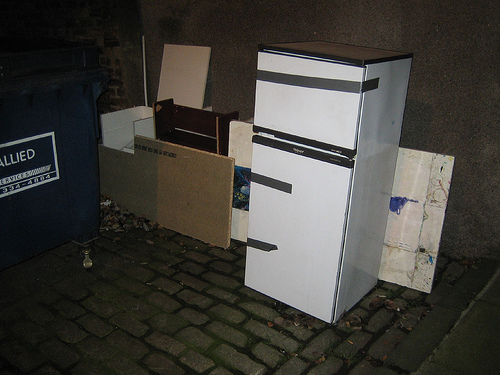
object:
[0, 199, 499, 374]
ground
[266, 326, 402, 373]
section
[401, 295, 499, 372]
section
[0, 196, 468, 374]
floor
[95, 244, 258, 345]
section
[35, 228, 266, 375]
section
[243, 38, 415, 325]
fridge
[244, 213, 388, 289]
part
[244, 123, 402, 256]
part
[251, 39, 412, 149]
part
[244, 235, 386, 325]
part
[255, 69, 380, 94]
tape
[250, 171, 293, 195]
taped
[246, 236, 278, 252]
taped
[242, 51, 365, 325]
door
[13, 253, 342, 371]
walkway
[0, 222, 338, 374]
bricks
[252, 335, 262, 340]
grout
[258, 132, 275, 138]
duct tape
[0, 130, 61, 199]
logo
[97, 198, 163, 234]
debris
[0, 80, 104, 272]
trash container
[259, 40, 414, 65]
top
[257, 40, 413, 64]
trim